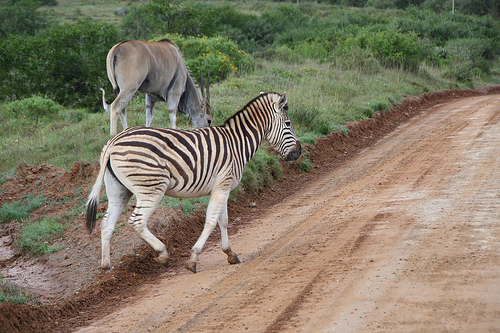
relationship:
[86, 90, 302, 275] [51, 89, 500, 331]
zebra walking on dirt road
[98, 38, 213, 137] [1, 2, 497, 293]
antelope grazing in grass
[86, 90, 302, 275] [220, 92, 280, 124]
zebra has mane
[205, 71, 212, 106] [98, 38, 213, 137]
horn on antelope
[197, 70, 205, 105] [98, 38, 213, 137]
horn on antelope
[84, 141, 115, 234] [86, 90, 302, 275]
tail of zebra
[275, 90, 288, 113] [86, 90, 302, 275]
ear of zebra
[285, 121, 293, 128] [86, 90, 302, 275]
eye of zebra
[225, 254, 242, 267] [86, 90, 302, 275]
hoof of zebra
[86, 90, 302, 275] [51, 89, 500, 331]
zebra on dirt road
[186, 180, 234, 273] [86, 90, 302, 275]
leg of zebra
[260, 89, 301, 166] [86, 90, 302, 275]
head of zebra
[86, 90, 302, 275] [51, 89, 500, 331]
zebra walking down dirt road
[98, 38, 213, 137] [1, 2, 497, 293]
antelope eating grass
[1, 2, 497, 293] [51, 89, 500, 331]
grass next to dirt road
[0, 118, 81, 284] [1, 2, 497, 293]
brush and grass